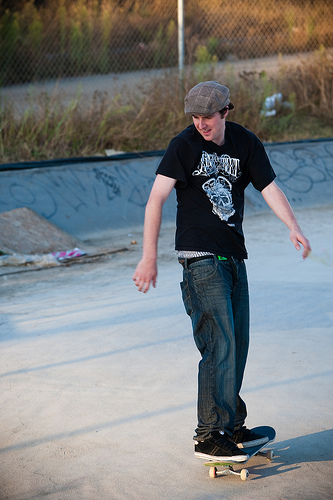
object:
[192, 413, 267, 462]
shoes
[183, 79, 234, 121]
hat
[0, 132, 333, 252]
concrete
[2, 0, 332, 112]
fence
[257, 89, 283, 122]
trash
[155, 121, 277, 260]
t shirt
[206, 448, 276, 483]
wheels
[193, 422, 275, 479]
skateboard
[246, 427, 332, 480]
shadows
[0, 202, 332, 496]
ground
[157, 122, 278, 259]
outskirts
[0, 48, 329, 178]
roadside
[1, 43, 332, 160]
grass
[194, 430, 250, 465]
foot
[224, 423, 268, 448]
foot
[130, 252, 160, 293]
hand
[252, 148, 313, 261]
arm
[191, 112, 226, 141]
face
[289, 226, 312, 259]
hand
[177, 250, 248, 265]
belt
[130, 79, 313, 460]
man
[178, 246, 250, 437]
jeans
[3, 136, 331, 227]
graffiti